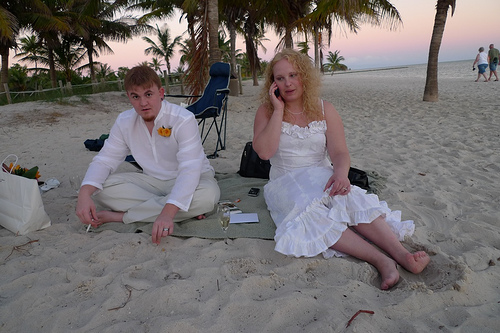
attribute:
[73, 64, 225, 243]
man — sitting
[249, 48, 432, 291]
woman — sitting, talking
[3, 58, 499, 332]
beach — sandy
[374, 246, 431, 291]
feet — bare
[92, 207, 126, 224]
foot — bare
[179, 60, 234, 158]
chair — blue, open, dark, portable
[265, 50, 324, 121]
hair — blonde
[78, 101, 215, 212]
shirt — white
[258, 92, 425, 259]
dress — white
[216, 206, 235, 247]
glass — sitting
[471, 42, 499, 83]
couple — standing, walking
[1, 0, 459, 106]
palm trees — green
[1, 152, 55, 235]
bag — beige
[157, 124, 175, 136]
flowers — orange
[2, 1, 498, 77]
sky — red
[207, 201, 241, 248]
flute — Champagne